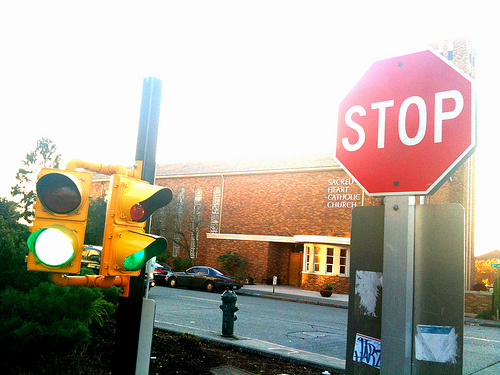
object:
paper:
[414, 322, 461, 364]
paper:
[354, 265, 382, 317]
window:
[206, 185, 223, 234]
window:
[172, 182, 184, 260]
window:
[158, 202, 165, 241]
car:
[162, 262, 244, 294]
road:
[148, 279, 500, 374]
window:
[189, 183, 203, 261]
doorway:
[286, 247, 304, 288]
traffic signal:
[118, 229, 166, 273]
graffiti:
[350, 332, 384, 369]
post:
[378, 195, 415, 374]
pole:
[133, 74, 161, 236]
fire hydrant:
[217, 285, 239, 339]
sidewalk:
[149, 315, 347, 370]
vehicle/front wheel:
[167, 274, 176, 286]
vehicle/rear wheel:
[204, 280, 213, 294]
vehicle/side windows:
[185, 264, 213, 275]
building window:
[208, 183, 224, 231]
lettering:
[324, 174, 361, 211]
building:
[85, 38, 493, 314]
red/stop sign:
[333, 42, 480, 198]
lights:
[23, 158, 174, 297]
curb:
[238, 284, 351, 308]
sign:
[343, 204, 466, 375]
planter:
[317, 281, 335, 298]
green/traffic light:
[28, 225, 76, 269]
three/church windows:
[170, 182, 226, 258]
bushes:
[0, 196, 129, 373]